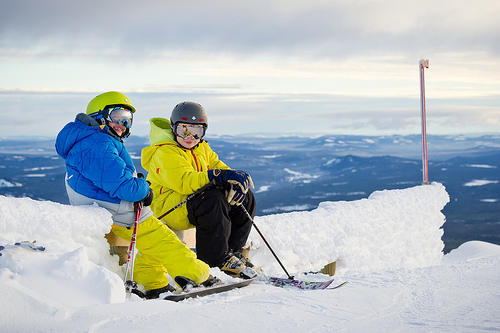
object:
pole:
[417, 57, 433, 186]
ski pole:
[233, 203, 296, 280]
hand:
[225, 182, 248, 207]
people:
[140, 101, 259, 280]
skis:
[301, 258, 341, 276]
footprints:
[381, 270, 412, 310]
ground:
[0, 237, 499, 333]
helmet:
[169, 100, 208, 135]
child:
[55, 91, 227, 300]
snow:
[2, 182, 498, 331]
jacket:
[139, 117, 235, 232]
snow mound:
[0, 180, 499, 333]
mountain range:
[5, 95, 499, 251]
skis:
[162, 278, 255, 302]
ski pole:
[122, 200, 145, 298]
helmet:
[86, 90, 136, 115]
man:
[56, 90, 239, 304]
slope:
[1, 180, 500, 333]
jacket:
[54, 111, 150, 227]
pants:
[185, 179, 256, 267]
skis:
[245, 277, 349, 292]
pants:
[105, 212, 210, 291]